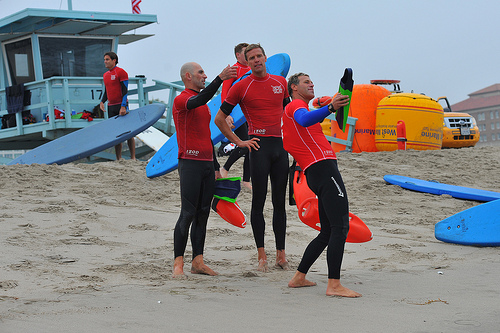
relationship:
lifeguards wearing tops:
[171, 61, 238, 279] [175, 112, 335, 153]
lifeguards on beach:
[171, 61, 238, 279] [15, 149, 494, 311]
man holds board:
[68, 55, 143, 164] [71, 119, 152, 144]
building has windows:
[2, 9, 119, 129] [9, 38, 118, 76]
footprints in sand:
[62, 201, 122, 261] [34, 174, 474, 311]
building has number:
[2, 9, 119, 129] [89, 87, 106, 100]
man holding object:
[279, 78, 360, 266] [320, 64, 365, 142]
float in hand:
[307, 203, 379, 244] [332, 97, 358, 117]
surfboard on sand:
[388, 168, 491, 212] [34, 174, 474, 311]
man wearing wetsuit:
[68, 55, 143, 164] [172, 90, 215, 233]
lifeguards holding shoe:
[171, 61, 238, 279] [213, 169, 244, 202]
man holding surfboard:
[68, 55, 143, 164] [54, 119, 162, 157]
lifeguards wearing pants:
[171, 61, 238, 279] [179, 163, 350, 250]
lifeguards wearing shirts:
[171, 61, 238, 279] [181, 95, 327, 145]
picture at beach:
[13, 17, 496, 324] [15, 149, 494, 311]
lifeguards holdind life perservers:
[93, 48, 354, 194] [208, 190, 274, 237]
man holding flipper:
[279, 78, 360, 266] [311, 71, 359, 125]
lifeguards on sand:
[171, 61, 238, 279] [34, 174, 474, 311]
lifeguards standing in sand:
[171, 61, 238, 279] [34, 174, 474, 311]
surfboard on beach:
[388, 168, 491, 212] [15, 149, 494, 311]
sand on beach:
[34, 174, 474, 311] [15, 149, 494, 311]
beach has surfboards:
[15, 149, 494, 311] [374, 173, 498, 239]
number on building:
[89, 87, 106, 100] [2, 9, 119, 129]